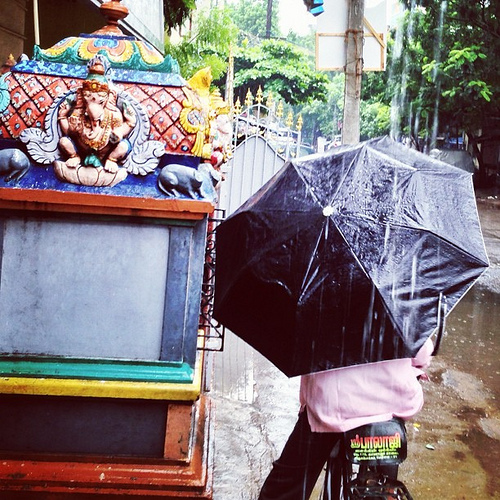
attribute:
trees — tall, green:
[197, 5, 482, 104]